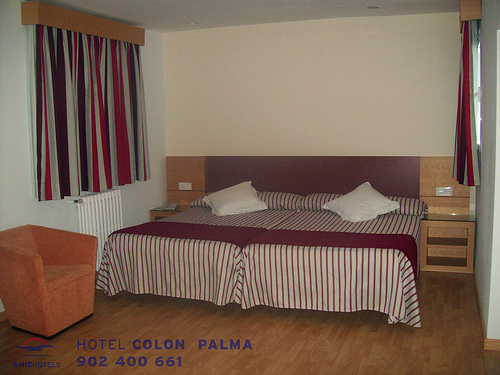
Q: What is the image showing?
A: It is showing a bedroom.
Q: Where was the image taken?
A: It was taken at the bedroom.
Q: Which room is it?
A: It is a bedroom.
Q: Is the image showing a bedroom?
A: Yes, it is showing a bedroom.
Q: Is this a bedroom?
A: Yes, it is a bedroom.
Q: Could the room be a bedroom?
A: Yes, it is a bedroom.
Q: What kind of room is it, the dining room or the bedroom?
A: It is the bedroom.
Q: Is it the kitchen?
A: No, it is the bedroom.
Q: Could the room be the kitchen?
A: No, it is the bedroom.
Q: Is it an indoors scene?
A: Yes, it is indoors.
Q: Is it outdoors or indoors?
A: It is indoors.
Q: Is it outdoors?
A: No, it is indoors.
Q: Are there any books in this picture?
A: No, there are no books.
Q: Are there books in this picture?
A: No, there are no books.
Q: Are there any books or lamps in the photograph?
A: No, there are no books or lamps.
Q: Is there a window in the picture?
A: Yes, there is a window.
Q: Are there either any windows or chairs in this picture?
A: Yes, there is a window.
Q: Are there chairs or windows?
A: Yes, there is a window.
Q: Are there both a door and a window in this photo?
A: No, there is a window but no doors.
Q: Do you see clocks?
A: No, there are no clocks.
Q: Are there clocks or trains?
A: No, there are no clocks or trains.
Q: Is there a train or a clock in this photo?
A: No, there are no clocks or trains.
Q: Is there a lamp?
A: No, there are no lamps.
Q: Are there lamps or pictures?
A: No, there are no lamps or pictures.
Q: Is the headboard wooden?
A: Yes, the headboard is wooden.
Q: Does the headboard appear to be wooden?
A: Yes, the headboard is wooden.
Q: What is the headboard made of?
A: The headboard is made of wood.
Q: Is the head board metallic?
A: No, the head board is wooden.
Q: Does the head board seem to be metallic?
A: No, the head board is wooden.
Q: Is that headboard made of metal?
A: No, the headboard is made of wood.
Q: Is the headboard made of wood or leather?
A: The headboard is made of wood.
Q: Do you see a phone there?
A: Yes, there is a phone.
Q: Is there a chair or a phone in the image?
A: Yes, there is a phone.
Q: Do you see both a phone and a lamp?
A: No, there is a phone but no lamps.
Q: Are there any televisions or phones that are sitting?
A: Yes, the phone is sitting.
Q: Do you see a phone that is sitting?
A: Yes, there is a phone that is sitting.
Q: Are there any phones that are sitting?
A: Yes, there is a phone that is sitting.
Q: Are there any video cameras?
A: No, there are no video cameras.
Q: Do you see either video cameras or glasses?
A: No, there are no video cameras or glasses.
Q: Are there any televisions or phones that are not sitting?
A: No, there is a phone but it is sitting.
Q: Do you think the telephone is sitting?
A: Yes, the telephone is sitting.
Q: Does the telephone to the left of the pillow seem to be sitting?
A: Yes, the phone is sitting.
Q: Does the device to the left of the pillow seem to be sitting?
A: Yes, the phone is sitting.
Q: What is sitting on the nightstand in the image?
A: The telephone is sitting on the nightstand.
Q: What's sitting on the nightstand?
A: The telephone is sitting on the nightstand.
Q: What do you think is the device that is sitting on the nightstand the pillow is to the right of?
A: The device is a phone.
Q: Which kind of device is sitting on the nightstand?
A: The device is a phone.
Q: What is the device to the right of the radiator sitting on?
A: The phone is sitting on the nightstand.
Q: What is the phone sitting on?
A: The phone is sitting on the nightstand.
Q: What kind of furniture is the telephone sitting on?
A: The telephone is sitting on the nightstand.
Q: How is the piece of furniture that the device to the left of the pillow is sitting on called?
A: The piece of furniture is a nightstand.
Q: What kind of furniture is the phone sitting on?
A: The telephone is sitting on the nightstand.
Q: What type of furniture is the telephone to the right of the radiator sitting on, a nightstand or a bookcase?
A: The telephone is sitting on a nightstand.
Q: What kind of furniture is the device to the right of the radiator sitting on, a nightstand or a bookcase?
A: The telephone is sitting on a nightstand.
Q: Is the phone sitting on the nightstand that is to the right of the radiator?
A: Yes, the phone is sitting on the nightstand.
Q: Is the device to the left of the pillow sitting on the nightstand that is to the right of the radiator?
A: Yes, the phone is sitting on the nightstand.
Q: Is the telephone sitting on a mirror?
A: No, the telephone is sitting on the nightstand.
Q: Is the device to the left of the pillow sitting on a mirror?
A: No, the telephone is sitting on the nightstand.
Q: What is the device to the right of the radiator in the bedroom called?
A: The device is a phone.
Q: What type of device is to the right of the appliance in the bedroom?
A: The device is a phone.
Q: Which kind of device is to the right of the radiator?
A: The device is a phone.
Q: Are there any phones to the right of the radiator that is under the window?
A: Yes, there is a phone to the right of the radiator.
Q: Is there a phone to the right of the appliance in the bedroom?
A: Yes, there is a phone to the right of the radiator.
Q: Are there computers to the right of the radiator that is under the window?
A: No, there is a phone to the right of the radiator.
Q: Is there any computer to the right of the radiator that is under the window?
A: No, there is a phone to the right of the radiator.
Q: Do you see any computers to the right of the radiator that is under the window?
A: No, there is a phone to the right of the radiator.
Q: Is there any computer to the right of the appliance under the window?
A: No, there is a phone to the right of the radiator.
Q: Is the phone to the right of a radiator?
A: Yes, the phone is to the right of a radiator.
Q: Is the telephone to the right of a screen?
A: No, the telephone is to the right of a radiator.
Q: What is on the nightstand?
A: The phone is on the nightstand.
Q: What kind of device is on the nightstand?
A: The device is a phone.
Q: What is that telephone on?
A: The telephone is on the nightstand.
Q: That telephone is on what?
A: The telephone is on the nightstand.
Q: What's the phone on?
A: The telephone is on the nightstand.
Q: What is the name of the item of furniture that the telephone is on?
A: The piece of furniture is a nightstand.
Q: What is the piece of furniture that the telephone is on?
A: The piece of furniture is a nightstand.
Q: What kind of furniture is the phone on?
A: The telephone is on the nightstand.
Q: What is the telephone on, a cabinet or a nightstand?
A: The telephone is on a nightstand.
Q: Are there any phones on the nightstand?
A: Yes, there is a phone on the nightstand.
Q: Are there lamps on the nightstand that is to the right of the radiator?
A: No, there is a phone on the nightstand.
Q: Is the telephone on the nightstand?
A: Yes, the telephone is on the nightstand.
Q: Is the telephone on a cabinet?
A: No, the telephone is on the nightstand.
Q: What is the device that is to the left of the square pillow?
A: The device is a phone.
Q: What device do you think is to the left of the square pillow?
A: The device is a phone.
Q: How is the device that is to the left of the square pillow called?
A: The device is a phone.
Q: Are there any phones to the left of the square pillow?
A: Yes, there is a phone to the left of the pillow.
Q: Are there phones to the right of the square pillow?
A: No, the phone is to the left of the pillow.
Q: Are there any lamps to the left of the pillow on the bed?
A: No, there is a phone to the left of the pillow.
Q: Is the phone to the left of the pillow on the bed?
A: Yes, the phone is to the left of the pillow.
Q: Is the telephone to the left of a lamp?
A: No, the telephone is to the left of the pillow.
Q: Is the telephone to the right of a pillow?
A: No, the telephone is to the left of a pillow.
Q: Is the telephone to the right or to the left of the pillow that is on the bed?
A: The telephone is to the left of the pillow.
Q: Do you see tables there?
A: Yes, there is a table.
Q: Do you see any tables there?
A: Yes, there is a table.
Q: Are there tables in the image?
A: Yes, there is a table.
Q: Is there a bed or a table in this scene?
A: Yes, there is a table.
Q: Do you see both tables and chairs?
A: Yes, there are both a table and a chair.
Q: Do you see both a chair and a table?
A: Yes, there are both a table and a chair.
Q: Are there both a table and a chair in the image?
A: Yes, there are both a table and a chair.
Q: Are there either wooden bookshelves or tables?
A: Yes, there is a wood table.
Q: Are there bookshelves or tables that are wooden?
A: Yes, the table is wooden.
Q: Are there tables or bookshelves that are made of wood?
A: Yes, the table is made of wood.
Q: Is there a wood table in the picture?
A: Yes, there is a wood table.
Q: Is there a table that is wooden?
A: Yes, there is a table that is wooden.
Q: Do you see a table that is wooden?
A: Yes, there is a table that is wooden.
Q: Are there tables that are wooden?
A: Yes, there is a table that is wooden.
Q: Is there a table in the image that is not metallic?
A: Yes, there is a wooden table.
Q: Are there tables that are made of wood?
A: Yes, there is a table that is made of wood.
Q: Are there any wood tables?
A: Yes, there is a table that is made of wood.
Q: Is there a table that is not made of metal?
A: Yes, there is a table that is made of wood.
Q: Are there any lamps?
A: No, there are no lamps.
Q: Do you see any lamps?
A: No, there are no lamps.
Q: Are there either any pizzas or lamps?
A: No, there are no lamps or pizzas.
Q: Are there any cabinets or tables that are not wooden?
A: No, there is a table but it is wooden.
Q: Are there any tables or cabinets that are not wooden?
A: No, there is a table but it is wooden.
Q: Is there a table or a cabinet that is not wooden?
A: No, there is a table but it is wooden.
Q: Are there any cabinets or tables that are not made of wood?
A: No, there is a table but it is made of wood.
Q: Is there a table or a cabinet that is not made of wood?
A: No, there is a table but it is made of wood.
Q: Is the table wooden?
A: Yes, the table is wooden.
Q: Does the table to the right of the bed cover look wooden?
A: Yes, the table is wooden.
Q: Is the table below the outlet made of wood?
A: Yes, the table is made of wood.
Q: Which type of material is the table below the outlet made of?
A: The table is made of wood.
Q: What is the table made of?
A: The table is made of wood.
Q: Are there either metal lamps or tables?
A: No, there is a table but it is wooden.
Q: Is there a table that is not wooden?
A: No, there is a table but it is wooden.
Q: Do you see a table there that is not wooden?
A: No, there is a table but it is wooden.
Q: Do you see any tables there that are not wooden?
A: No, there is a table but it is wooden.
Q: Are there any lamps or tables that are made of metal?
A: No, there is a table but it is made of wood.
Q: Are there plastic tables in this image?
A: No, there is a table but it is made of wood.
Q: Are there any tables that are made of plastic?
A: No, there is a table but it is made of wood.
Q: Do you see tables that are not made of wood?
A: No, there is a table but it is made of wood.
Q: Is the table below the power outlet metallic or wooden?
A: The table is wooden.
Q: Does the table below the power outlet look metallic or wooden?
A: The table is wooden.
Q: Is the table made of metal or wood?
A: The table is made of wood.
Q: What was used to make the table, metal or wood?
A: The table is made of wood.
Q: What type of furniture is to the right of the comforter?
A: The piece of furniture is a table.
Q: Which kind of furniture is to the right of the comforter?
A: The piece of furniture is a table.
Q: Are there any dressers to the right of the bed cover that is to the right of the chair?
A: No, there is a table to the right of the comforter.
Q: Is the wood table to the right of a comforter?
A: Yes, the table is to the right of a comforter.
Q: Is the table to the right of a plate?
A: No, the table is to the right of a comforter.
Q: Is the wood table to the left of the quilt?
A: No, the table is to the right of the quilt.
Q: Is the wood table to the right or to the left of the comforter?
A: The table is to the right of the comforter.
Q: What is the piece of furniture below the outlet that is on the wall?
A: The piece of furniture is a table.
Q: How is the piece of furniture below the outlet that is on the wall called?
A: The piece of furniture is a table.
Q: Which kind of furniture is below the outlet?
A: The piece of furniture is a table.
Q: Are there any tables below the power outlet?
A: Yes, there is a table below the power outlet.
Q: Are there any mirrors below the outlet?
A: No, there is a table below the outlet.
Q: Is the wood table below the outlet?
A: Yes, the table is below the outlet.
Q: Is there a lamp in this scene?
A: No, there are no lamps.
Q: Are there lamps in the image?
A: No, there are no lamps.